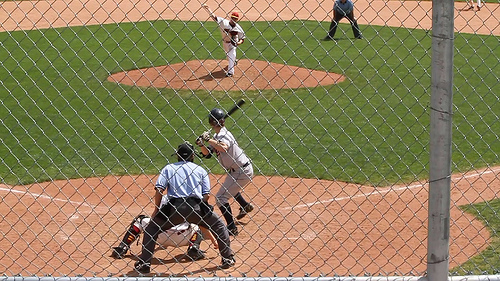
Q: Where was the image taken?
A: It was taken at the field.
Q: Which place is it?
A: It is a field.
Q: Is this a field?
A: Yes, it is a field.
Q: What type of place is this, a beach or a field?
A: It is a field.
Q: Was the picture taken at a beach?
A: No, the picture was taken in a field.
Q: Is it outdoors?
A: Yes, it is outdoors.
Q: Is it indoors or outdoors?
A: It is outdoors.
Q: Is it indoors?
A: No, it is outdoors.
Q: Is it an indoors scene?
A: No, it is outdoors.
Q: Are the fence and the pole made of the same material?
A: Yes, both the fence and the pole are made of metal.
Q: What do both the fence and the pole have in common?
A: The material, both the fence and the pole are metallic.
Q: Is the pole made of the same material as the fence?
A: Yes, both the pole and the fence are made of metal.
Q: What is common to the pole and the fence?
A: The material, both the pole and the fence are metallic.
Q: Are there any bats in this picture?
A: Yes, there is a bat.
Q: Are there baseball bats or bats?
A: Yes, there is a bat.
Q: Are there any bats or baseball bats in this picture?
A: Yes, there is a bat.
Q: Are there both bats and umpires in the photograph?
A: Yes, there are both a bat and an umpire.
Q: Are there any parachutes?
A: No, there are no parachutes.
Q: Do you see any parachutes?
A: No, there are no parachutes.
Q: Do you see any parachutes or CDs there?
A: No, there are no parachutes or cds.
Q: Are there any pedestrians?
A: No, there are no pedestrians.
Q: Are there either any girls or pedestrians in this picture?
A: No, there are no pedestrians or girls.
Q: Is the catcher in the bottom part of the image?
A: Yes, the catcher is in the bottom of the image.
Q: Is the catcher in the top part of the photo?
A: No, the catcher is in the bottom of the image.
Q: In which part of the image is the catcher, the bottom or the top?
A: The catcher is in the bottom of the image.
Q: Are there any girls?
A: No, there are no girls.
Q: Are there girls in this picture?
A: No, there are no girls.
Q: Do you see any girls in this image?
A: No, there are no girls.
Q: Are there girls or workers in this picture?
A: No, there are no girls or workers.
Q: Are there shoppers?
A: No, there are no shoppers.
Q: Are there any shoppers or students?
A: No, there are no shoppers or students.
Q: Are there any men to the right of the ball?
A: Yes, there is a man to the right of the ball.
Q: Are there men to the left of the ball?
A: No, the man is to the right of the ball.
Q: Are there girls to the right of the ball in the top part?
A: No, there is a man to the right of the ball.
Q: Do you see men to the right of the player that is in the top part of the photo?
A: Yes, there is a man to the right of the player.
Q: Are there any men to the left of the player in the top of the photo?
A: No, the man is to the right of the player.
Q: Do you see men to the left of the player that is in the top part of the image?
A: No, the man is to the right of the player.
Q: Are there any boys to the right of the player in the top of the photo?
A: No, there is a man to the right of the player.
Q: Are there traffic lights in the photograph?
A: No, there are no traffic lights.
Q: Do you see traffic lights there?
A: No, there are no traffic lights.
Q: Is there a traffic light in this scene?
A: No, there are no traffic lights.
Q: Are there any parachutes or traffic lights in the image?
A: No, there are no traffic lights or parachutes.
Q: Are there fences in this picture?
A: Yes, there is a fence.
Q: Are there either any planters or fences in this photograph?
A: Yes, there is a fence.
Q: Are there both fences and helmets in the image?
A: Yes, there are both a fence and a helmet.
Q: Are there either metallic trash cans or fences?
A: Yes, there is a metal fence.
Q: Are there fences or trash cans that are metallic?
A: Yes, the fence is metallic.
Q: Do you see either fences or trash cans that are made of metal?
A: Yes, the fence is made of metal.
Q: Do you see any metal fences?
A: Yes, there is a metal fence.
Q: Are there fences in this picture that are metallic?
A: Yes, there is a fence that is metallic.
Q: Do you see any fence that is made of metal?
A: Yes, there is a fence that is made of metal.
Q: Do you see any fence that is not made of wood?
A: Yes, there is a fence that is made of metal.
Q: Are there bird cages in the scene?
A: No, there are no bird cages.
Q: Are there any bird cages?
A: No, there are no bird cages.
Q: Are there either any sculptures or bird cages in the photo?
A: No, there are no bird cages or sculptures.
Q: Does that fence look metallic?
A: Yes, the fence is metallic.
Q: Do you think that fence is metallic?
A: Yes, the fence is metallic.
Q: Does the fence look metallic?
A: Yes, the fence is metallic.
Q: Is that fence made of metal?
A: Yes, the fence is made of metal.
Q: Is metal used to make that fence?
A: Yes, the fence is made of metal.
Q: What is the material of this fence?
A: The fence is made of metal.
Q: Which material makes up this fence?
A: The fence is made of metal.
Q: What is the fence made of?
A: The fence is made of metal.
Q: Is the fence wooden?
A: No, the fence is metallic.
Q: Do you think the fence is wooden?
A: No, the fence is metallic.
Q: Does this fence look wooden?
A: No, the fence is metallic.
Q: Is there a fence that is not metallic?
A: No, there is a fence but it is metallic.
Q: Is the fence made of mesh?
A: No, the fence is made of metal.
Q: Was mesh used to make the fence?
A: No, the fence is made of metal.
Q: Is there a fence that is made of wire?
A: No, there is a fence but it is made of metal.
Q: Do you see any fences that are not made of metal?
A: No, there is a fence but it is made of metal.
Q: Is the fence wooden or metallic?
A: The fence is metallic.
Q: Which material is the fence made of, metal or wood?
A: The fence is made of metal.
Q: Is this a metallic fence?
A: Yes, this is a metallic fence.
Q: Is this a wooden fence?
A: No, this is a metallic fence.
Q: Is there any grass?
A: Yes, there is grass.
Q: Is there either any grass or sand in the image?
A: Yes, there is grass.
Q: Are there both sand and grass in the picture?
A: No, there is grass but no sand.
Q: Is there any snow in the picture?
A: No, there is no snow.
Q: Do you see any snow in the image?
A: No, there is no snow.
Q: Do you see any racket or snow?
A: No, there are no snow or rackets.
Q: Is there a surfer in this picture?
A: No, there are no surfers.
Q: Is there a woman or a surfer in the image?
A: No, there are no surfers or women.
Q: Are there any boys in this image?
A: No, there are no boys.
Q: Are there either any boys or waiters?
A: No, there are no boys or waiters.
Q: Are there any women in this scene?
A: No, there are no women.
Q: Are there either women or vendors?
A: No, there are no women or vendors.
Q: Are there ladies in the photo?
A: No, there are no ladies.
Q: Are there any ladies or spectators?
A: No, there are no ladies or spectators.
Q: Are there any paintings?
A: No, there are no paintings.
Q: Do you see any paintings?
A: No, there are no paintings.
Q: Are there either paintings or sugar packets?
A: No, there are no paintings or sugar packets.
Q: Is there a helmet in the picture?
A: Yes, there is a helmet.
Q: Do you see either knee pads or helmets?
A: Yes, there is a helmet.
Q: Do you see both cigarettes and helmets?
A: No, there is a helmet but no cigarettes.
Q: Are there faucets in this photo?
A: No, there are no faucets.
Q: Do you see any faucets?
A: No, there are no faucets.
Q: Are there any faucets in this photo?
A: No, there are no faucets.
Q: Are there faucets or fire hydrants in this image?
A: No, there are no faucets or fire hydrants.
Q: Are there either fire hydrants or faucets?
A: No, there are no faucets or fire hydrants.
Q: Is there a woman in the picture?
A: No, there are no women.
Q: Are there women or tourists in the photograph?
A: No, there are no women or tourists.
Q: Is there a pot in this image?
A: No, there are no pots.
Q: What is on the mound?
A: The pitcher is on the mound.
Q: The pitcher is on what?
A: The pitcher is on the mound.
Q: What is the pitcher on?
A: The pitcher is on the mound.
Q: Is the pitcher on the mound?
A: Yes, the pitcher is on the mound.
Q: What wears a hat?
A: The pitcher wears a hat.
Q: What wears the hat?
A: The pitcher wears a hat.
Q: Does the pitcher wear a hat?
A: Yes, the pitcher wears a hat.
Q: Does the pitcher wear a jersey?
A: No, the pitcher wears a hat.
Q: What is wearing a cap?
A: The pitcher is wearing a cap.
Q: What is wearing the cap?
A: The pitcher is wearing a cap.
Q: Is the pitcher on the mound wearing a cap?
A: Yes, the pitcher is wearing a cap.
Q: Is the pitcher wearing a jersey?
A: No, the pitcher is wearing a cap.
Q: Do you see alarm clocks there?
A: No, there are no alarm clocks.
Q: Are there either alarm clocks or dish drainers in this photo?
A: No, there are no alarm clocks or dish drainers.